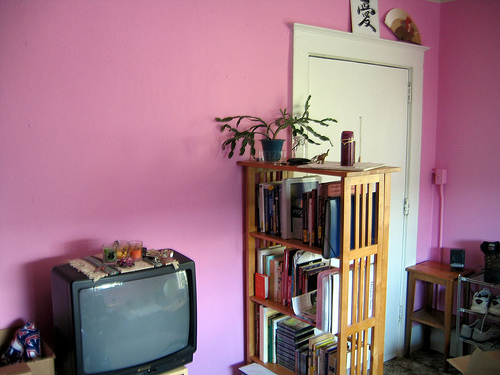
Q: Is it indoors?
A: Yes, it is indoors.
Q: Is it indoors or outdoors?
A: It is indoors.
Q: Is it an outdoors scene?
A: No, it is indoors.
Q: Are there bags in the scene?
A: No, there are no bags.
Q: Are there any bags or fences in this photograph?
A: No, there are no bags or fences.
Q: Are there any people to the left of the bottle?
A: Yes, there is a person to the left of the bottle.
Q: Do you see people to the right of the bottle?
A: No, the person is to the left of the bottle.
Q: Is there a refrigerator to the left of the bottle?
A: No, there is a person to the left of the bottle.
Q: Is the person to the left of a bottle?
A: Yes, the person is to the left of a bottle.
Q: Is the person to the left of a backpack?
A: No, the person is to the left of a bottle.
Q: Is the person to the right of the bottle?
A: No, the person is to the left of the bottle.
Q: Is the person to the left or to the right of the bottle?
A: The person is to the left of the bottle.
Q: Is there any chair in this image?
A: No, there are no chairs.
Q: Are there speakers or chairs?
A: No, there are no chairs or speakers.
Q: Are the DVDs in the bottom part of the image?
A: Yes, the DVDs are in the bottom of the image.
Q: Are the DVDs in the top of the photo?
A: No, the DVDs are in the bottom of the image.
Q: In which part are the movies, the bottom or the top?
A: The movies are in the bottom of the image.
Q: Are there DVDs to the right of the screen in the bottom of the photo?
A: Yes, there are DVDs to the right of the screen.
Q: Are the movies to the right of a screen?
A: Yes, the movies are to the right of a screen.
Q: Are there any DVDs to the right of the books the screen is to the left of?
A: Yes, there are DVDs to the right of the books.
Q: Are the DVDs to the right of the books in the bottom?
A: Yes, the DVDs are to the right of the books.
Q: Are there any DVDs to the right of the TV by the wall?
A: Yes, there are DVDs to the right of the television.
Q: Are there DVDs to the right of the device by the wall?
A: Yes, there are DVDs to the right of the television.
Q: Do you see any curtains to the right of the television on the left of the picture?
A: No, there are DVDs to the right of the TV.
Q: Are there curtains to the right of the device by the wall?
A: No, there are DVDs to the right of the TV.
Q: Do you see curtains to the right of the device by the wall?
A: No, there are DVDs to the right of the TV.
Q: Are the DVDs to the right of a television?
A: Yes, the DVDs are to the right of a television.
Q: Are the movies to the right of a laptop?
A: No, the movies are to the right of a television.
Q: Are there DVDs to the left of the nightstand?
A: Yes, there are DVDs to the left of the nightstand.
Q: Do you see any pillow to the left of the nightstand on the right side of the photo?
A: No, there are DVDs to the left of the nightstand.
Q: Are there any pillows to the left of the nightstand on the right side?
A: No, there are DVDs to the left of the nightstand.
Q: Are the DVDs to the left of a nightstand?
A: Yes, the DVDs are to the left of a nightstand.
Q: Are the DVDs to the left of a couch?
A: No, the DVDs are to the left of a nightstand.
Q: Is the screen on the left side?
A: Yes, the screen is on the left of the image.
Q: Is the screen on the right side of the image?
A: No, the screen is on the left of the image.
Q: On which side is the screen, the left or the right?
A: The screen is on the left of the image.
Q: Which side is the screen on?
A: The screen is on the left of the image.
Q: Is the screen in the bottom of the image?
A: Yes, the screen is in the bottom of the image.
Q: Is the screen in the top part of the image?
A: No, the screen is in the bottom of the image.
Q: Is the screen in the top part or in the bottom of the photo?
A: The screen is in the bottom of the image.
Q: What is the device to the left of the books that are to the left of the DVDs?
A: The device is a screen.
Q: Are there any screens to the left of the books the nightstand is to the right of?
A: Yes, there is a screen to the left of the books.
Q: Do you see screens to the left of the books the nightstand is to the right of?
A: Yes, there is a screen to the left of the books.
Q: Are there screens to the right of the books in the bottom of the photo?
A: No, the screen is to the left of the books.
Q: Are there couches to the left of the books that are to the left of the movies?
A: No, there is a screen to the left of the books.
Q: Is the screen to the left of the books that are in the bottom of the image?
A: Yes, the screen is to the left of the books.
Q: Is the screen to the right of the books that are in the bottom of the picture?
A: No, the screen is to the left of the books.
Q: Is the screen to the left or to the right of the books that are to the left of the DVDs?
A: The screen is to the left of the books.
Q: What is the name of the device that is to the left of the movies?
A: The device is a screen.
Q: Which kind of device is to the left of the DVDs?
A: The device is a screen.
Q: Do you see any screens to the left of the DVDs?
A: Yes, there is a screen to the left of the DVDs.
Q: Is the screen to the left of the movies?
A: Yes, the screen is to the left of the movies.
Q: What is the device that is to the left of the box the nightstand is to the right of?
A: The device is a screen.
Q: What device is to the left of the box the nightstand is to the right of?
A: The device is a screen.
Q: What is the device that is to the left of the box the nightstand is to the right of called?
A: The device is a screen.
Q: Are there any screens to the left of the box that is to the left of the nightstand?
A: Yes, there is a screen to the left of the box.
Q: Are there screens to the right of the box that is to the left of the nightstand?
A: No, the screen is to the left of the box.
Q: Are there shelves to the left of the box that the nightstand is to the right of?
A: No, there is a screen to the left of the box.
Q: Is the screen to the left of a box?
A: Yes, the screen is to the left of a box.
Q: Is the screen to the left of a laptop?
A: No, the screen is to the left of a box.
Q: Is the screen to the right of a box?
A: No, the screen is to the left of a box.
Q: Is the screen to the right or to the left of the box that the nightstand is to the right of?
A: The screen is to the left of the box.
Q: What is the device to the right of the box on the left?
A: The device is a screen.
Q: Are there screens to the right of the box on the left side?
A: Yes, there is a screen to the right of the box.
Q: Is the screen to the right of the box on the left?
A: Yes, the screen is to the right of the box.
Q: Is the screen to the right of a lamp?
A: No, the screen is to the right of the box.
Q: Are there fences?
A: No, there are no fences.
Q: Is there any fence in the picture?
A: No, there are no fences.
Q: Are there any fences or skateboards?
A: No, there are no fences or skateboards.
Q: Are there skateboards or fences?
A: No, there are no fences or skateboards.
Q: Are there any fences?
A: No, there are no fences.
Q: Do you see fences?
A: No, there are no fences.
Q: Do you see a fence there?
A: No, there are no fences.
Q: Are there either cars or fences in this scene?
A: No, there are no fences or cars.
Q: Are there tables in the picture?
A: Yes, there is a table.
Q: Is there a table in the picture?
A: Yes, there is a table.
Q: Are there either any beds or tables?
A: Yes, there is a table.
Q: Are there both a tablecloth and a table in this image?
A: No, there is a table but no tablecloths.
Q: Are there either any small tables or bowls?
A: Yes, there is a small table.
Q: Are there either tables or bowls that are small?
A: Yes, the table is small.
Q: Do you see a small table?
A: Yes, there is a small table.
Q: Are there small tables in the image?
A: Yes, there is a small table.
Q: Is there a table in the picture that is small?
A: Yes, there is a table that is small.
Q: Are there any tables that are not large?
A: Yes, there is a small table.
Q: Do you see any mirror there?
A: No, there are no mirrors.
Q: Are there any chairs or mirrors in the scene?
A: No, there are no mirrors or chairs.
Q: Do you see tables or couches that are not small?
A: No, there is a table but it is small.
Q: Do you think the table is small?
A: Yes, the table is small.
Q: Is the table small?
A: Yes, the table is small.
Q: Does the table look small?
A: Yes, the table is small.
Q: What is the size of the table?
A: The table is small.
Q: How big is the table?
A: The table is small.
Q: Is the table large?
A: No, the table is small.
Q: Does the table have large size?
A: No, the table is small.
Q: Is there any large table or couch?
A: No, there is a table but it is small.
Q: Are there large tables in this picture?
A: No, there is a table but it is small.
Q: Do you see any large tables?
A: No, there is a table but it is small.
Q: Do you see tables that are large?
A: No, there is a table but it is small.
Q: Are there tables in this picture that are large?
A: No, there is a table but it is small.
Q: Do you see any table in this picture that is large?
A: No, there is a table but it is small.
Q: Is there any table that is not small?
A: No, there is a table but it is small.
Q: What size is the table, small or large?
A: The table is small.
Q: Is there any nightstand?
A: Yes, there is a nightstand.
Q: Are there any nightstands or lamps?
A: Yes, there is a nightstand.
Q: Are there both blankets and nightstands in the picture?
A: No, there is a nightstand but no blankets.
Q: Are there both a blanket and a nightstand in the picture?
A: No, there is a nightstand but no blankets.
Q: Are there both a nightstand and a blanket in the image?
A: No, there is a nightstand but no blankets.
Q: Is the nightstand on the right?
A: Yes, the nightstand is on the right of the image.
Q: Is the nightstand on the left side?
A: No, the nightstand is on the right of the image.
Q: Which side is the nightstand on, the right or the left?
A: The nightstand is on the right of the image.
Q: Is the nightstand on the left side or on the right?
A: The nightstand is on the right of the image.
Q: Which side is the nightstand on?
A: The nightstand is on the right of the image.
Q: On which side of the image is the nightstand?
A: The nightstand is on the right of the image.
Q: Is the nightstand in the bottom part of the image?
A: Yes, the nightstand is in the bottom of the image.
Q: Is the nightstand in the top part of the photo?
A: No, the nightstand is in the bottom of the image.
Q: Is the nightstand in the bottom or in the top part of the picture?
A: The nightstand is in the bottom of the image.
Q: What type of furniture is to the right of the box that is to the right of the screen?
A: The piece of furniture is a nightstand.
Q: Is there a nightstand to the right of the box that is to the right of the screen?
A: Yes, there is a nightstand to the right of the box.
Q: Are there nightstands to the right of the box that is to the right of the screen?
A: Yes, there is a nightstand to the right of the box.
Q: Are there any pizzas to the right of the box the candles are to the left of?
A: No, there is a nightstand to the right of the box.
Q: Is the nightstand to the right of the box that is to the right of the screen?
A: Yes, the nightstand is to the right of the box.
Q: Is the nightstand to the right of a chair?
A: No, the nightstand is to the right of the box.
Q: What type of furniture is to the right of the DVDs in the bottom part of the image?
A: The piece of furniture is a nightstand.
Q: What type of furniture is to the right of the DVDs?
A: The piece of furniture is a nightstand.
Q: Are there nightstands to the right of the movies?
A: Yes, there is a nightstand to the right of the movies.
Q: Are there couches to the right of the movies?
A: No, there is a nightstand to the right of the movies.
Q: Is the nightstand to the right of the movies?
A: Yes, the nightstand is to the right of the movies.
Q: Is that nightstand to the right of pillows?
A: No, the nightstand is to the right of the movies.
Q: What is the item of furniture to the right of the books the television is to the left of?
A: The piece of furniture is a nightstand.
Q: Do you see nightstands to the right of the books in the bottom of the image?
A: Yes, there is a nightstand to the right of the books.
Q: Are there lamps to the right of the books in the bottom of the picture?
A: No, there is a nightstand to the right of the books.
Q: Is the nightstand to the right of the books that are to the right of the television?
A: Yes, the nightstand is to the right of the books.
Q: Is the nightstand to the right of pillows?
A: No, the nightstand is to the right of the books.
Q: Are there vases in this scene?
A: No, there are no vases.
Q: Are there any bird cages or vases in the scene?
A: No, there are no vases or bird cages.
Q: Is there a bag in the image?
A: No, there are no bags.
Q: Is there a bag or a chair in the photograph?
A: No, there are no bags or chairs.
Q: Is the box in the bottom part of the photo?
A: Yes, the box is in the bottom of the image.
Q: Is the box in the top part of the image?
A: No, the box is in the bottom of the image.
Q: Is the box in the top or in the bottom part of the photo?
A: The box is in the bottom of the image.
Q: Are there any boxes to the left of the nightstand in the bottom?
A: Yes, there is a box to the left of the nightstand.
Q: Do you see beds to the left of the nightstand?
A: No, there is a box to the left of the nightstand.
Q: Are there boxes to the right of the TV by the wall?
A: Yes, there is a box to the right of the TV.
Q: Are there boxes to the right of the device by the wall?
A: Yes, there is a box to the right of the TV.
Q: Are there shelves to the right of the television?
A: No, there is a box to the right of the television.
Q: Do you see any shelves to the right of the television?
A: No, there is a box to the right of the television.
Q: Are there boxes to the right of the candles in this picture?
A: Yes, there is a box to the right of the candles.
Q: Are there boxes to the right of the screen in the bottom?
A: Yes, there is a box to the right of the screen.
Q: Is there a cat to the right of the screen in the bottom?
A: No, there is a box to the right of the screen.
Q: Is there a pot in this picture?
A: Yes, there is a pot.